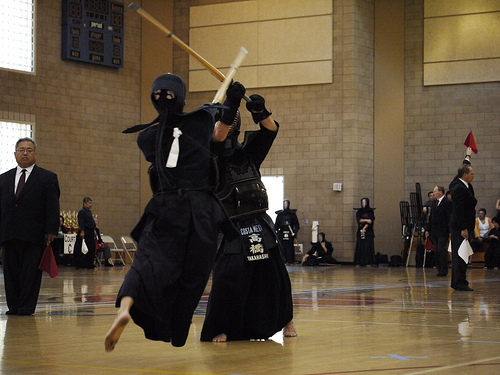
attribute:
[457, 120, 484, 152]
flag — red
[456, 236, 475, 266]
hanky — white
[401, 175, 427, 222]
gates — metal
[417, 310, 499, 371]
floor — shiny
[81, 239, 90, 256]
hanky — White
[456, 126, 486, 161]
cloth — red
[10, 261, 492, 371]
floor — shiny,  shining,  gym's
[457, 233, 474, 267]
cloth — white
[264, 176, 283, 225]
door —  open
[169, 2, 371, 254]
wall —  far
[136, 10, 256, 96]
stick fighting — of stick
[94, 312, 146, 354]
foot —  bare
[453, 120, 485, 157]
cloth —  raised ,   red 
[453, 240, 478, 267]
flag — white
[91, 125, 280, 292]
robes —  long,  black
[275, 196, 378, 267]
participants —  other,  waiting their turn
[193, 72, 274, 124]
gloves — black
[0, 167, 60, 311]
suit — black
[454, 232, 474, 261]
cloth — white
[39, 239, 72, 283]
cloth — red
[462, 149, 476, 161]
wristwatch —  for wrist,  with black band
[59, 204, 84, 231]
trophies — golden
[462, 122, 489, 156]
hanky — red